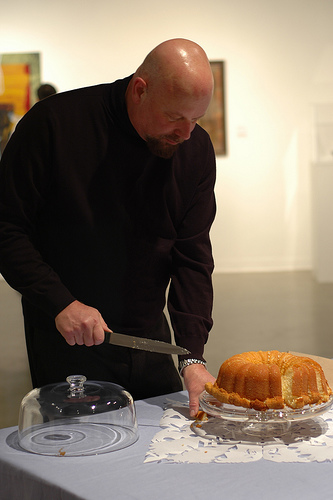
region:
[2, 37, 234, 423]
a man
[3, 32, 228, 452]
the man wears all black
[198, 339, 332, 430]
a cake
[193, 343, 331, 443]
the cake is on a glass serving dish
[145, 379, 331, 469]
a white paper is under the cake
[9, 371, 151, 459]
a glass cover for the cake dish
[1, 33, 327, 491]
the man is cutting the cake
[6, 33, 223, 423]
the man is holding a knife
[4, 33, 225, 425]
the man is bald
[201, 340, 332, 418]
the cake has no frosting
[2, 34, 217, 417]
Man standing at table cutting cake.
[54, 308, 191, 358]
Man holding knife in right hand.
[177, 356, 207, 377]
Watch on man's left wrist.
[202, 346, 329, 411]
Cake on cake platter.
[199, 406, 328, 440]
Edge of cake platter.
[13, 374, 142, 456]
Top for cake platter.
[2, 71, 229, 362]
Man dressed in black long sleeve shirt.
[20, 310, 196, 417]
Man dressed in black pants.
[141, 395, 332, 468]
White doily under cake platter.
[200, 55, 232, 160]
Edge of picture hanging on wall.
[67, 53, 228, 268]
man wearing black shirt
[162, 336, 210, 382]
man wearing silver bracelet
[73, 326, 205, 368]
man holding silver knife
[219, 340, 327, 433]
sponge cake on plate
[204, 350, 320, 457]
cake on glass plate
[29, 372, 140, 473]
cake plate top on table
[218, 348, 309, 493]
cake on white table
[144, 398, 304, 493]
white table cloth on table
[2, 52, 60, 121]
painted art behind man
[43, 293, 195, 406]
man wearing black pants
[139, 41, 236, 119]
a man with no hair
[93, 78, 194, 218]
a man wearing a black shirt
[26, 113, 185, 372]
a man wearing black pants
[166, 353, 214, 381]
a man wearing a silver watch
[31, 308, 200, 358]
a man holding a knife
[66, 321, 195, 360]
a long knife with a black handle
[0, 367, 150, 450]
a glass lid for a cake plate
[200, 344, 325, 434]
a cake on top of a cake plate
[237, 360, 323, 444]
a glass cake plate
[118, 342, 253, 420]
a man cutting a cake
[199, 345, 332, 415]
Vanilla bundt cake with part of it sliced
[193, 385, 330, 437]
Glass cake plate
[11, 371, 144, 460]
Glass lid with know to cake plate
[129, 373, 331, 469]
White doilie under cake plate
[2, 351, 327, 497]
Table with gray cloth tablecloth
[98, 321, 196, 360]
Cake knife with black handle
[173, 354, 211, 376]
Silver chain watch band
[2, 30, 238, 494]
Man cutting cake with knife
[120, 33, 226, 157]
Man with bald head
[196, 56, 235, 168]
Picture in dark brown frame hung on white wall